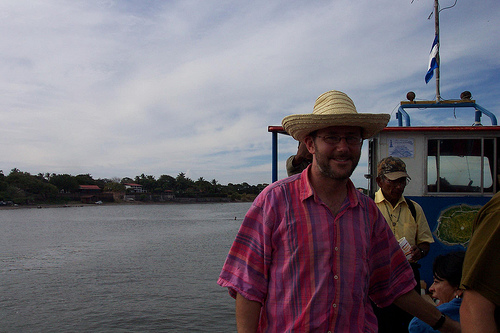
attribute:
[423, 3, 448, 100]
pole — metal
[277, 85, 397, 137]
hat — wide brim, woven, underside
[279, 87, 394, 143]
hat — straw, beige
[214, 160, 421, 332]
shirt — plaid, red, pink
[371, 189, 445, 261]
shirt — yellow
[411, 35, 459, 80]
flag — blue, white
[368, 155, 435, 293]
man — older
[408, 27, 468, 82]
flag — blue and white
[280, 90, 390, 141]
hat — straw